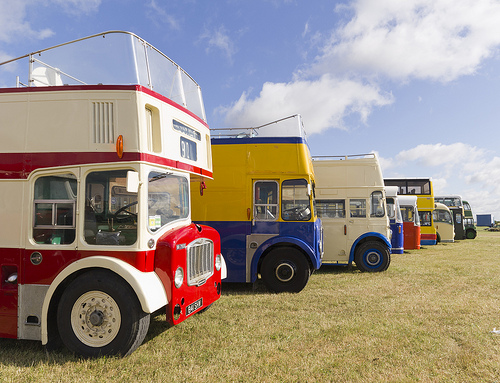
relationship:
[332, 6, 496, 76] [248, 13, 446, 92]
clouds in sky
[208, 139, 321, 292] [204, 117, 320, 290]
front of rv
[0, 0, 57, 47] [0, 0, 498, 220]
clouds in sky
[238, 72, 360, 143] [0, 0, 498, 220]
clouds in sky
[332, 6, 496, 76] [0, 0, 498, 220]
clouds in sky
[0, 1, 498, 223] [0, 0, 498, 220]
clouds in sky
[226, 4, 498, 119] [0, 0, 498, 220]
clouds in sky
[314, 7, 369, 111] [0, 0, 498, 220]
clouds in sky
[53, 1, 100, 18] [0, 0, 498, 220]
clouds in sky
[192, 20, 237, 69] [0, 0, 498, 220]
clouds in sky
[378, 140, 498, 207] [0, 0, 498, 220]
clouds in sky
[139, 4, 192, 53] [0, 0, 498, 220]
clouds in sky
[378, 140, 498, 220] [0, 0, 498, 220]
clouds in sky